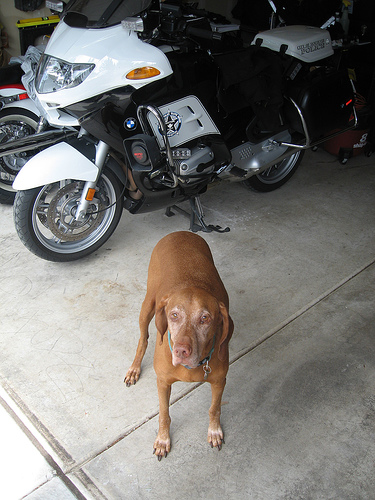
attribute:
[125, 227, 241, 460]
brown dog — short haired, brown 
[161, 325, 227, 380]
blue collar — blue 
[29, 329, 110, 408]
thin marks — thin 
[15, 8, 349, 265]
motorcycle — parked 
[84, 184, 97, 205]
orange reflector — orange 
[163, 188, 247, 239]
kickstand — down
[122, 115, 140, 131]
logo — blue , white 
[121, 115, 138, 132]
logo — small, BMW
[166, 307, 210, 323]
eyes — tiny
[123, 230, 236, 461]
dog — brown, short haired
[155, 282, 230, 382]
dog — brown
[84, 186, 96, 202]
reflector — orange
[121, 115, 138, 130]
logo — small, blue and white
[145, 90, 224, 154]
motor — white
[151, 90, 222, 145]
motor — white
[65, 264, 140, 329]
spot — brown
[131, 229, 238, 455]
dog — brown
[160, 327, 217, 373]
collar — blue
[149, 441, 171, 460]
nails — long, black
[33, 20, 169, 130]
motor — white